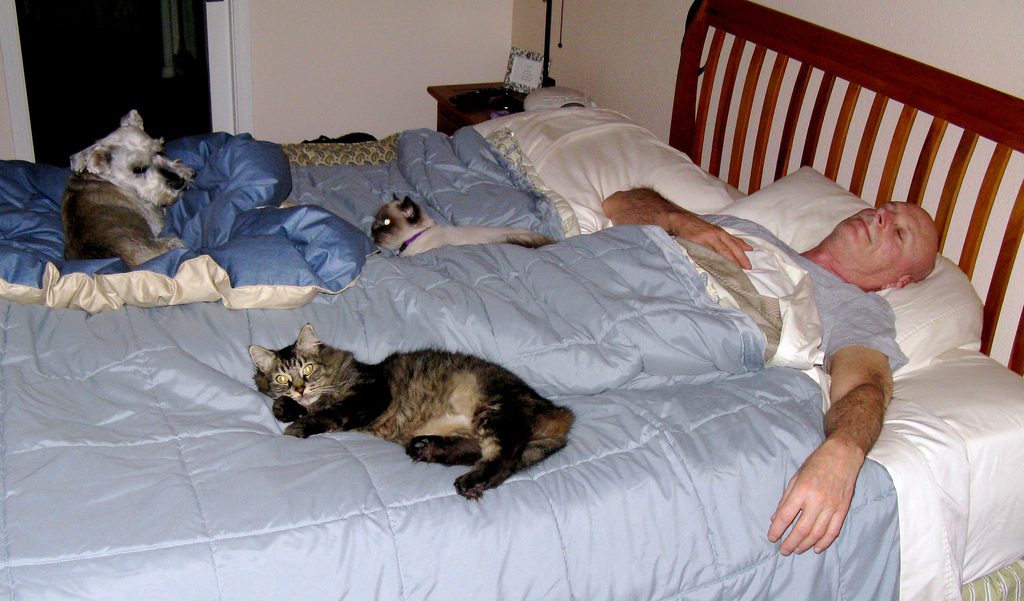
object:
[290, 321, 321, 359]
ear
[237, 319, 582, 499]
cat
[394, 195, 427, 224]
ear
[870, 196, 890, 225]
nose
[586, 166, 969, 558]
man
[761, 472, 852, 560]
finger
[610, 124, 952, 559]
man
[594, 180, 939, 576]
man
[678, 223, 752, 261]
finger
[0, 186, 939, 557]
person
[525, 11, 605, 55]
pull string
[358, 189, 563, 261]
cat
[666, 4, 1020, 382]
wooden headboard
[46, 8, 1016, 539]
bed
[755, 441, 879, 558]
hand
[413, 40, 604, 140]
stand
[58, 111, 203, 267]
dog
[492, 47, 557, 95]
card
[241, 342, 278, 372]
ear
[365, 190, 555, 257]
animal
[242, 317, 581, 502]
animal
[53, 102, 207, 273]
animal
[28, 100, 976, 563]
scene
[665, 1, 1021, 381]
headboard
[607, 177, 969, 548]
man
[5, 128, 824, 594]
sheets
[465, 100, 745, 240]
pillow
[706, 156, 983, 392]
pillow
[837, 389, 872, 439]
hair